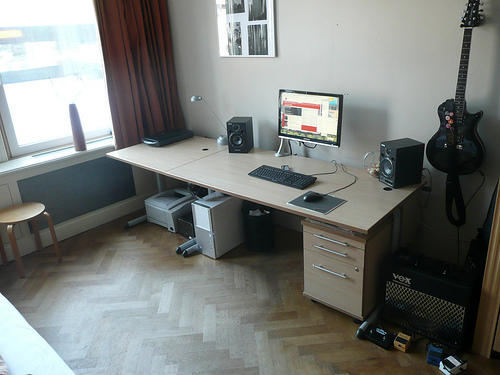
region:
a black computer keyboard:
[248, 162, 315, 192]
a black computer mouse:
[302, 190, 319, 202]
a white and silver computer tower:
[188, 189, 244, 262]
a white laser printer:
[140, 189, 195, 231]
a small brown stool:
[0, 196, 65, 276]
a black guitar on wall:
[429, 1, 497, 175]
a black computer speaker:
[220, 114, 255, 155]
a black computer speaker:
[376, 137, 422, 188]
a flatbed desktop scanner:
[137, 121, 194, 149]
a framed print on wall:
[209, 0, 280, 62]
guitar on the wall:
[421, 0, 491, 213]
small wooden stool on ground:
[7, 195, 66, 259]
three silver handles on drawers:
[293, 240, 363, 289]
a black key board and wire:
[240, 156, 320, 191]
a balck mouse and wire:
[280, 165, 360, 227]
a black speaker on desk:
[344, 139, 429, 221]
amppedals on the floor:
[302, 334, 487, 374]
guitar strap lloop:
[427, 175, 474, 257]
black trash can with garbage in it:
[225, 193, 275, 263]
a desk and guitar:
[17, 129, 464, 289]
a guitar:
[424, 23, 484, 217]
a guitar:
[433, 35, 458, 159]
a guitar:
[449, 45, 496, 145]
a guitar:
[444, 42, 479, 173]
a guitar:
[418, 53, 498, 308]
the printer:
[135, 192, 183, 223]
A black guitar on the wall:
[431, 35, 491, 184]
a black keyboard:
[254, 159, 316, 188]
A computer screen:
[278, 86, 342, 146]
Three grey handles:
[313, 233, 350, 283]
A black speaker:
[218, 113, 258, 153]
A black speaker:
[366, 133, 420, 188]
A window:
[10, 105, 79, 143]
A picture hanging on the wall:
[211, 13, 278, 73]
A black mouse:
[302, 191, 329, 208]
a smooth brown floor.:
[95, 262, 282, 355]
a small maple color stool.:
[0, 180, 67, 275]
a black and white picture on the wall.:
[210, 0, 290, 60]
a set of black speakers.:
[210, 120, 430, 180]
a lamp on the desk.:
[181, 85, 226, 150]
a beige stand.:
[95, 125, 401, 316]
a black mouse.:
[292, 177, 362, 207]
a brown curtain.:
[81, 5, 181, 135]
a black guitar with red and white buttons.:
[430, 2, 490, 222]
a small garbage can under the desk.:
[240, 201, 278, 247]